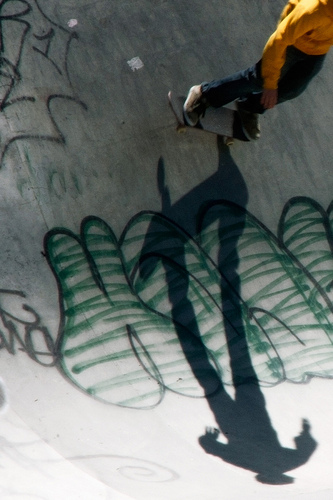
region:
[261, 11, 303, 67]
arm of a person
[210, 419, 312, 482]
shadow of a person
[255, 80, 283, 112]
hand of a person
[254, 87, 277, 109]
finger of a person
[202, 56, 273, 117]
leg of a person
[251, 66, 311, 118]
leg of a person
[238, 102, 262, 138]
feet of a person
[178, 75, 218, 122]
feet of a person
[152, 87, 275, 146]
person on a skateboard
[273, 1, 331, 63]
person wearing yellow shirt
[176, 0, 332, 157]
this is a person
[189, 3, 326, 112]
the boy is skating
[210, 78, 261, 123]
these are the legs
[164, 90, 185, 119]
this is a skate board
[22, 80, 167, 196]
this is the floor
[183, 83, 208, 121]
this is a shoe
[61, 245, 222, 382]
the floor is caligraphed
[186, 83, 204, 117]
the shoe is brown in color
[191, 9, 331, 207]
This is a person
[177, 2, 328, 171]
This is a person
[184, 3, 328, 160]
This is a person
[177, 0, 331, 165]
This is a person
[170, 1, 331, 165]
This is a person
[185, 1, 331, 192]
This is a person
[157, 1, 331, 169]
This is a person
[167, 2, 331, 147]
This is a person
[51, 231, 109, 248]
green painted line on ground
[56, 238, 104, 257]
green painted line on ground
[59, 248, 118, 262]
green painted line on ground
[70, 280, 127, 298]
green painted line on ground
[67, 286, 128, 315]
green painted line on ground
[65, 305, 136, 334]
green painted line on ground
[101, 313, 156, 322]
green painted line on ground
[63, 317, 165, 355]
green painted line on ground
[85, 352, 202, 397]
green painted line on ground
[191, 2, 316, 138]
A person is standing up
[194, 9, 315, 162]
A person is playing.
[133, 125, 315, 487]
a shadow on the ramp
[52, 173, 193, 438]
graffit ont he ramp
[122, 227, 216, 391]
graffit ont he ramp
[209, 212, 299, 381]
graffit ont he ramp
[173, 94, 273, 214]
feet on the skateboard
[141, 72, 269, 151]
a skateboard on the ramp